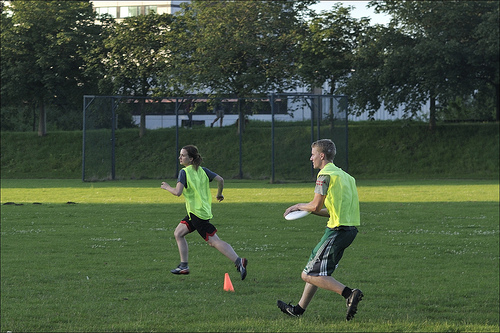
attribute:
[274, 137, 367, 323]
man — young, playing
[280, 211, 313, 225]
frisbee — round, white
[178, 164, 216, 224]
top — green, neon green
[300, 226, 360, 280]
shorts — black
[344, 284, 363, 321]
shoe — black, athletic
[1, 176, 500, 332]
field — grassy, green, shady, sunny, grass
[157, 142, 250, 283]
woman — young, running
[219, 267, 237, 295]
boundary marker — orange, small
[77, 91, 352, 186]
goal — blue, metal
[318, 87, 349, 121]
fence — chain link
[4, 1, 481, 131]
building — white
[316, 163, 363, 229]
vest — yellow